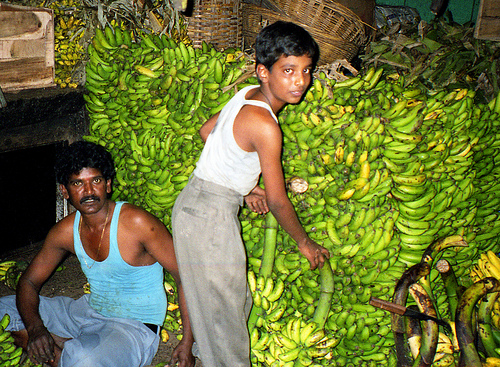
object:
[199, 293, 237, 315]
part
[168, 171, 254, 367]
trouser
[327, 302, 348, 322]
part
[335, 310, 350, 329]
banana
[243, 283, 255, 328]
edge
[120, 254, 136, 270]
edge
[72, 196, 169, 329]
vest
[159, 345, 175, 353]
part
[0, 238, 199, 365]
floor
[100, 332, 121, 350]
part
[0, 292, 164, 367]
jeans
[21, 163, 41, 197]
part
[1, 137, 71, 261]
hollow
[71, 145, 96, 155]
part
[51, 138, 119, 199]
hairs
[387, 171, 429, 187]
bananas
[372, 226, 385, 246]
bananas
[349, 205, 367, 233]
bananas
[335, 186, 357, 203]
bananas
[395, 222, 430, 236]
bananas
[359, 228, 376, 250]
bananas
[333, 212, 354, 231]
bananas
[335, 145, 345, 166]
bananas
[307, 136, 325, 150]
bananas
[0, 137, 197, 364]
man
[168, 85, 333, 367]
body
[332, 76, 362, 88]
bananas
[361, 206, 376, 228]
bananas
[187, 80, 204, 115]
bananas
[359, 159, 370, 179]
bananas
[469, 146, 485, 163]
bananas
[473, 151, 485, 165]
bananas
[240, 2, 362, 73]
baskets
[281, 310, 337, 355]
banana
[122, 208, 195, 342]
arm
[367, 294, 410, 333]
handle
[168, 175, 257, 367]
long